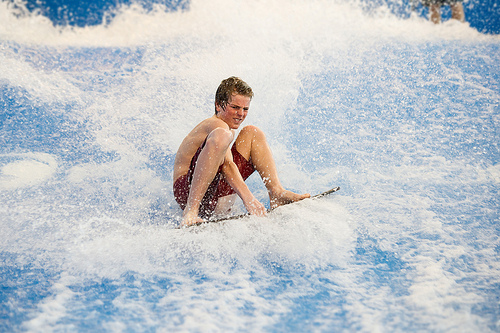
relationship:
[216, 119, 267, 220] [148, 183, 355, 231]
arm holding board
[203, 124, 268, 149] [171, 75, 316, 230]
knees of surfer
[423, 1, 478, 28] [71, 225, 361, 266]
legs in wave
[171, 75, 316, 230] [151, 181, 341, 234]
surfer sitting on board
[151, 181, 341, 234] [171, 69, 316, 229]
board of surfer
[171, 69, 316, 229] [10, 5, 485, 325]
surfer in ocean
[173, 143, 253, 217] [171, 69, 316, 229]
shorts of surfer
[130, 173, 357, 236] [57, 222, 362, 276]
surfboard making wave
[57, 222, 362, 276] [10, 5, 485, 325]
wave in ocean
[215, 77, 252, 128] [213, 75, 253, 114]
head with hair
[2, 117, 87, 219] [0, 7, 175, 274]
swirl in wave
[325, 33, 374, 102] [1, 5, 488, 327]
big splashes in water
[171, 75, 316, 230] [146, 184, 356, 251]
surfer on surfboard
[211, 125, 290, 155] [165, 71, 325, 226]
knees of boy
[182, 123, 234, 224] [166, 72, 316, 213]
leg of boy